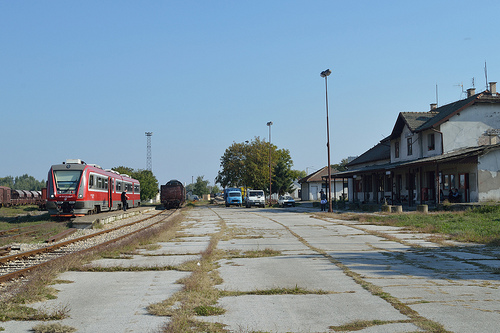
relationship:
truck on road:
[221, 184, 246, 208] [10, 204, 497, 329]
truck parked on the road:
[246, 190, 266, 209] [10, 204, 497, 329]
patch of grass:
[178, 247, 214, 295] [3, 199, 499, 331]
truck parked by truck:
[245, 190, 265, 208] [224, 187, 242, 206]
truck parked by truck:
[224, 187, 242, 206] [245, 190, 265, 208]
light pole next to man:
[318, 60, 335, 219] [302, 181, 327, 213]